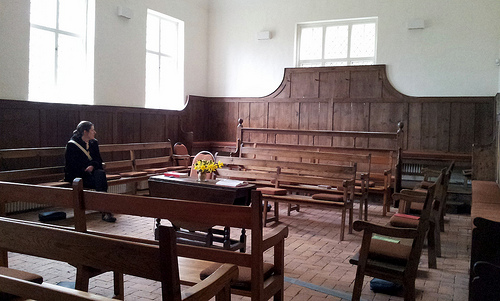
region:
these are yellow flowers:
[188, 150, 233, 177]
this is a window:
[279, 12, 400, 102]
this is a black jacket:
[64, 135, 105, 185]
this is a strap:
[63, 132, 103, 165]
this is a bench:
[186, 120, 416, 237]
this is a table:
[138, 157, 253, 258]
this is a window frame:
[140, 4, 195, 116]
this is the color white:
[419, 45, 449, 69]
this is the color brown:
[305, 249, 325, 282]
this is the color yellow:
[206, 164, 211, 169]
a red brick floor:
[5, 190, 465, 296]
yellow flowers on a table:
[195, 155, 217, 180]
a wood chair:
[347, 190, 427, 291]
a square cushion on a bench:
[200, 250, 275, 280]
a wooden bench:
[215, 140, 401, 195]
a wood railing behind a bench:
[230, 111, 410, 158]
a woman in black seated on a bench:
[65, 117, 117, 222]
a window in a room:
[140, 10, 191, 110]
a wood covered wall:
[280, 70, 390, 151]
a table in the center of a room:
[146, 164, 258, 256]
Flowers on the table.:
[185, 126, 270, 204]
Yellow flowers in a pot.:
[171, 142, 254, 196]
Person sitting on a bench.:
[33, 92, 198, 274]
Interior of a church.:
[52, 63, 482, 293]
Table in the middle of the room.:
[137, 142, 314, 232]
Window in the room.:
[279, 12, 395, 107]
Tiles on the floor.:
[302, 232, 327, 272]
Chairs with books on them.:
[351, 176, 471, 293]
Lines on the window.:
[294, 20, 403, 77]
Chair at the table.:
[148, 147, 292, 231]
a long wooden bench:
[2, 137, 174, 194]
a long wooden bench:
[2, 214, 239, 299]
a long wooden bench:
[183, 148, 357, 239]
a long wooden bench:
[232, 141, 394, 209]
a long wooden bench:
[341, 187, 438, 292]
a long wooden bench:
[396, 162, 455, 262]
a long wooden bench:
[468, 151, 498, 291]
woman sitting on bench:
[63, 121, 118, 218]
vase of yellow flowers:
[192, 156, 217, 182]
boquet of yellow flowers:
[178, 141, 230, 195]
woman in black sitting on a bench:
[48, 102, 142, 210]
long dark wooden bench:
[226, 113, 417, 190]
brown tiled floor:
[155, 174, 475, 295]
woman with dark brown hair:
[52, 109, 126, 189]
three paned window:
[280, 11, 411, 85]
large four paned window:
[139, 8, 196, 118]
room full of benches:
[25, 98, 451, 283]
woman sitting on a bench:
[58, 115, 150, 224]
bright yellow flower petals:
[195, 155, 222, 177]